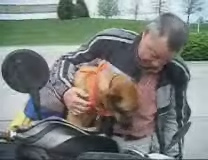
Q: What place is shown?
A: It is a street.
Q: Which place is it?
A: It is a street.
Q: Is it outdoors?
A: Yes, it is outdoors.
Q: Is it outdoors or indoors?
A: It is outdoors.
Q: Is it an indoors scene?
A: No, it is outdoors.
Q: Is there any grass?
A: Yes, there is grass.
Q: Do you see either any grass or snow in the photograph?
A: Yes, there is grass.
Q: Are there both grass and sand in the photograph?
A: No, there is grass but no sand.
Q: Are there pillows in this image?
A: No, there are no pillows.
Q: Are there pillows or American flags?
A: No, there are no pillows or American flags.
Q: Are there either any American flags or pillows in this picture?
A: No, there are no pillows or American flags.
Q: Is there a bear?
A: No, there are no bears.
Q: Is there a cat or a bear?
A: No, there are no bears or cats.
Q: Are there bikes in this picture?
A: Yes, there is a bike.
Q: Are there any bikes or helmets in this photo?
A: Yes, there is a bike.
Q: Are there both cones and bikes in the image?
A: No, there is a bike but no cones.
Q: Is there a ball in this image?
A: No, there are no balls.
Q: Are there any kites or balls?
A: No, there are no balls or kites.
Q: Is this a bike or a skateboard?
A: This is a bike.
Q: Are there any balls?
A: No, there are no balls.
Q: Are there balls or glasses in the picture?
A: No, there are no balls or glasses.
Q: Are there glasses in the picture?
A: No, there are no glasses.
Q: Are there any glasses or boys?
A: No, there are no glasses or boys.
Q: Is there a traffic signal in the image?
A: No, there are no traffic lights.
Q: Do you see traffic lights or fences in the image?
A: No, there are no traffic lights or fences.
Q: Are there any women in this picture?
A: No, there are no women.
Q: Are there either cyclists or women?
A: No, there are no women or cyclists.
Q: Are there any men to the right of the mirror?
A: Yes, there is a man to the right of the mirror.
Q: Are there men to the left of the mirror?
A: No, the man is to the right of the mirror.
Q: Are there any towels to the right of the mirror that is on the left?
A: No, there is a man to the right of the mirror.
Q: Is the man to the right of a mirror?
A: Yes, the man is to the right of a mirror.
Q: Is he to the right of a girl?
A: No, the man is to the right of a mirror.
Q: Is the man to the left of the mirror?
A: No, the man is to the right of the mirror.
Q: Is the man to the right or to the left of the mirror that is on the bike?
A: The man is to the right of the mirror.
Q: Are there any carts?
A: No, there are no carts.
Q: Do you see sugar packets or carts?
A: No, there are no carts or sugar packets.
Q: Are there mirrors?
A: Yes, there is a mirror.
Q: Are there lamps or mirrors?
A: Yes, there is a mirror.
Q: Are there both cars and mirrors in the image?
A: No, there is a mirror but no cars.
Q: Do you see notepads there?
A: No, there are no notepads.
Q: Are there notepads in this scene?
A: No, there are no notepads.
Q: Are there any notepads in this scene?
A: No, there are no notepads.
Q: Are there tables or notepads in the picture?
A: No, there are no notepads or tables.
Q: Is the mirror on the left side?
A: Yes, the mirror is on the left of the image.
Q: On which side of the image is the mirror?
A: The mirror is on the left of the image.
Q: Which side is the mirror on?
A: The mirror is on the left of the image.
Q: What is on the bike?
A: The mirror is on the bike.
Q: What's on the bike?
A: The mirror is on the bike.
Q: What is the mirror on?
A: The mirror is on the bike.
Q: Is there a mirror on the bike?
A: Yes, there is a mirror on the bike.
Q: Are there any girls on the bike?
A: No, there is a mirror on the bike.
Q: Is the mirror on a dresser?
A: No, the mirror is on the bike.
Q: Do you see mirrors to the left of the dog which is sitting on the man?
A: Yes, there is a mirror to the left of the dog.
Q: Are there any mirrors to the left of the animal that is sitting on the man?
A: Yes, there is a mirror to the left of the dog.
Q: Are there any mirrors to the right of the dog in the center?
A: No, the mirror is to the left of the dog.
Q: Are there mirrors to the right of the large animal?
A: No, the mirror is to the left of the dog.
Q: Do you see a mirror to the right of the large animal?
A: No, the mirror is to the left of the dog.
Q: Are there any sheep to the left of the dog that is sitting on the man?
A: No, there is a mirror to the left of the dog.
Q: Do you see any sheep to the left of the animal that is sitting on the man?
A: No, there is a mirror to the left of the dog.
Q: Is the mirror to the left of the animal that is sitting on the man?
A: Yes, the mirror is to the left of the dog.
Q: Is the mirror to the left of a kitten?
A: No, the mirror is to the left of the dog.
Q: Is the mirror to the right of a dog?
A: No, the mirror is to the left of a dog.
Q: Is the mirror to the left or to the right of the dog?
A: The mirror is to the left of the dog.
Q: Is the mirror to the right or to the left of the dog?
A: The mirror is to the left of the dog.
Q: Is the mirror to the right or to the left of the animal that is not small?
A: The mirror is to the left of the dog.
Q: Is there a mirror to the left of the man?
A: Yes, there is a mirror to the left of the man.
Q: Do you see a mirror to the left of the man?
A: Yes, there is a mirror to the left of the man.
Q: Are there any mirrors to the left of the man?
A: Yes, there is a mirror to the left of the man.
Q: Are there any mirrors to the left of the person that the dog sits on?
A: Yes, there is a mirror to the left of the man.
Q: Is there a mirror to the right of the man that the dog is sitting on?
A: No, the mirror is to the left of the man.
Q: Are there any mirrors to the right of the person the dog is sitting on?
A: No, the mirror is to the left of the man.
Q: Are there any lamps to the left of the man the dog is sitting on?
A: No, there is a mirror to the left of the man.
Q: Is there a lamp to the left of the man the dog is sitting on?
A: No, there is a mirror to the left of the man.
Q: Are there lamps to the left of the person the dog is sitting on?
A: No, there is a mirror to the left of the man.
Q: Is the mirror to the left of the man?
A: Yes, the mirror is to the left of the man.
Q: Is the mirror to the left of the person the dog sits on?
A: Yes, the mirror is to the left of the man.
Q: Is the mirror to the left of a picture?
A: No, the mirror is to the left of the man.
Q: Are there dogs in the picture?
A: Yes, there is a dog.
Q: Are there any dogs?
A: Yes, there is a dog.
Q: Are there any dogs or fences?
A: Yes, there is a dog.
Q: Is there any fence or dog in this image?
A: Yes, there is a dog.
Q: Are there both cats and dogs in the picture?
A: No, there is a dog but no cats.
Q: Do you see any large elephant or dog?
A: Yes, there is a large dog.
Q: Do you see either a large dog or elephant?
A: Yes, there is a large dog.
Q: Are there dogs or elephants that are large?
A: Yes, the dog is large.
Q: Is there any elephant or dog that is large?
A: Yes, the dog is large.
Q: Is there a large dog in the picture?
A: Yes, there is a large dog.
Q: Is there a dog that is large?
A: Yes, there is a dog that is large.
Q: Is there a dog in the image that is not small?
A: Yes, there is a large dog.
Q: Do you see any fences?
A: No, there are no fences.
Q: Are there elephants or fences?
A: No, there are no fences or elephants.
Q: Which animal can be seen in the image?
A: The animal is a dog.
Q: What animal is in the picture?
A: The animal is a dog.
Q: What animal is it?
A: The animal is a dog.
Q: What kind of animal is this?
A: This is a dog.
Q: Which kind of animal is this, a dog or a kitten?
A: This is a dog.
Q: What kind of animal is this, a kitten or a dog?
A: This is a dog.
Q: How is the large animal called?
A: The animal is a dog.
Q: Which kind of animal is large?
A: The animal is a dog.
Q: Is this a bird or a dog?
A: This is a dog.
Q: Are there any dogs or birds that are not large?
A: No, there is a dog but it is large.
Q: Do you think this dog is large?
A: Yes, the dog is large.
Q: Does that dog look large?
A: Yes, the dog is large.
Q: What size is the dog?
A: The dog is large.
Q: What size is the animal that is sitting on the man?
A: The dog is large.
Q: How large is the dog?
A: The dog is large.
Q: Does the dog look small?
A: No, the dog is large.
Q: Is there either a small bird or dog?
A: No, there is a dog but it is large.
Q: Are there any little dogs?
A: No, there is a dog but it is large.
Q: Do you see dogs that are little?
A: No, there is a dog but it is large.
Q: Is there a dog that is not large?
A: No, there is a dog but it is large.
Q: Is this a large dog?
A: Yes, this is a large dog.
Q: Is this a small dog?
A: No, this is a large dog.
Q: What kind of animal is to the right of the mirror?
A: The animal is a dog.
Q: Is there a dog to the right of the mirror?
A: Yes, there is a dog to the right of the mirror.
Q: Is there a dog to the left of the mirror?
A: No, the dog is to the right of the mirror.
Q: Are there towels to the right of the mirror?
A: No, there is a dog to the right of the mirror.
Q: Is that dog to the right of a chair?
A: No, the dog is to the right of the mirror.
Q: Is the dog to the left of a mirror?
A: No, the dog is to the right of a mirror.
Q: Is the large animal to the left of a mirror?
A: No, the dog is to the right of a mirror.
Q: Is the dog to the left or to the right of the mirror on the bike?
A: The dog is to the right of the mirror.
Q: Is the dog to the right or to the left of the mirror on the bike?
A: The dog is to the right of the mirror.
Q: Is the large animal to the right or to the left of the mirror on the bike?
A: The dog is to the right of the mirror.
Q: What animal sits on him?
A: The dog sits on the man.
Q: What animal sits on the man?
A: The dog sits on the man.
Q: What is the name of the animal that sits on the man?
A: The animal is a dog.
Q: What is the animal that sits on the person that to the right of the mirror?
A: The animal is a dog.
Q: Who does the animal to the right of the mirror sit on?
A: The dog sits on the man.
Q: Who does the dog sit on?
A: The dog sits on the man.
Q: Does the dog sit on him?
A: Yes, the dog sits on the man.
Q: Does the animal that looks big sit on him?
A: Yes, the dog sits on the man.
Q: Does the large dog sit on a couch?
A: No, the dog sits on the man.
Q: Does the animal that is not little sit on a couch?
A: No, the dog sits on the man.